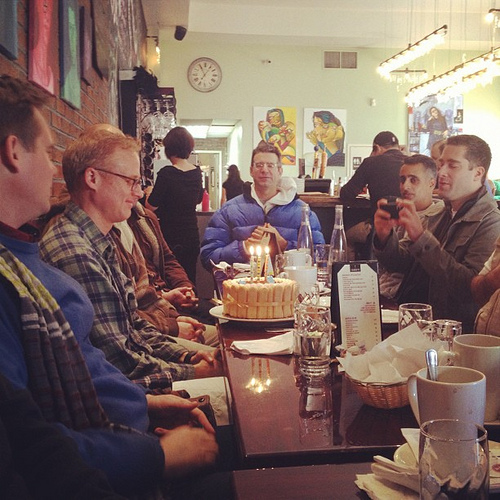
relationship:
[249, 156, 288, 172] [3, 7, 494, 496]
eyeglasses in photo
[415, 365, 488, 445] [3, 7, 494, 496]
cup in photo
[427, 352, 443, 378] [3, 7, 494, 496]
spoon in photo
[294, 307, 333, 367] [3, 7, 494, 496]
cup in photo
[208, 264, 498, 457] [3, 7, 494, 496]
table in photo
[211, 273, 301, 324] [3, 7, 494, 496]
cake in photo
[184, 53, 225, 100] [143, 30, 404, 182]
clock on wall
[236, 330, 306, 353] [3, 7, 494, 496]
serviette in photo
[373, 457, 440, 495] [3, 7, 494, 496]
serviette in photo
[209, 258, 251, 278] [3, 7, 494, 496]
serviette in photo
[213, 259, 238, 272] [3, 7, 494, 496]
serviette in photo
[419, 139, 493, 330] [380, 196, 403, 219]
man taking camera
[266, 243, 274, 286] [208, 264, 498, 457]
candle on table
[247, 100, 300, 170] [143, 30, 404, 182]
art on wall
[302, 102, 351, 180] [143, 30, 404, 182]
art on wall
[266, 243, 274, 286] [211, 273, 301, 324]
candle on cake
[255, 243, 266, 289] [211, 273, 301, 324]
candle on cake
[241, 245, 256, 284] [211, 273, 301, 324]
candle on cake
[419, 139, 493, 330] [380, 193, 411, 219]
man holding camera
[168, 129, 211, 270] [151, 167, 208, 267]
woman wearing dress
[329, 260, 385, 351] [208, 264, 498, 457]
menu on table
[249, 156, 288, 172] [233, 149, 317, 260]
eyeglasses on man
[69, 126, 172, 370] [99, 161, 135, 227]
man has skin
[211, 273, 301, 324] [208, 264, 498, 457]
cake on table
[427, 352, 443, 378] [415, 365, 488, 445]
spoon in mug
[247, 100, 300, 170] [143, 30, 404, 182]
painting on wall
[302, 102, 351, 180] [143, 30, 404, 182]
painting on wall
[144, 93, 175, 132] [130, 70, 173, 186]
glasses above bar